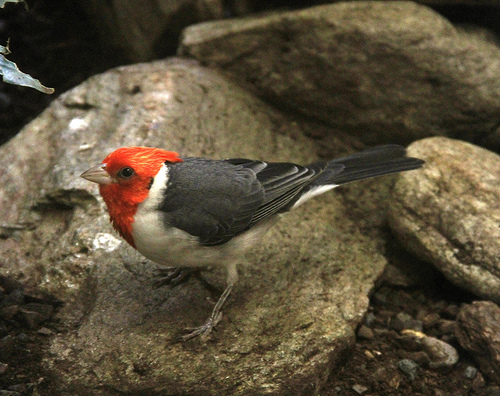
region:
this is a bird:
[55, 113, 431, 346]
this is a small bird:
[50, 113, 450, 365]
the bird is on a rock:
[60, 105, 467, 362]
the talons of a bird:
[155, 299, 266, 359]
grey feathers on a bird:
[172, 155, 368, 232]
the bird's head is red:
[67, 90, 463, 328]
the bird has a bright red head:
[51, 114, 204, 251]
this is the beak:
[81, 147, 113, 189]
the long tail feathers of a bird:
[300, 128, 435, 200]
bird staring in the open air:
[80, 152, 299, 303]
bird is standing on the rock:
[85, 116, 277, 329]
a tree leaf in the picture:
[2, 39, 48, 107]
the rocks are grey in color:
[48, 261, 178, 393]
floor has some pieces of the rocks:
[386, 292, 485, 393]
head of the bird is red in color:
[73, 143, 163, 205]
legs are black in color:
[161, 259, 237, 342]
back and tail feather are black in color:
[169, 161, 355, 210]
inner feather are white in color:
[118, 204, 265, 281]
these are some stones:
[148, 70, 355, 141]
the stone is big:
[161, 90, 237, 131]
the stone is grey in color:
[261, 272, 321, 337]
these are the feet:
[154, 262, 244, 348]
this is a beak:
[75, 157, 109, 188]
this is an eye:
[114, 164, 141, 181]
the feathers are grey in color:
[195, 165, 247, 218]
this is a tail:
[306, 137, 430, 206]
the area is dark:
[82, 38, 115, 53]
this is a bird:
[71, 130, 421, 307]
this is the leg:
[193, 277, 232, 329]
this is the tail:
[322, 133, 402, 191]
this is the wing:
[173, 175, 257, 226]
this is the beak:
[84, 167, 109, 181]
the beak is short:
[70, 159, 110, 195]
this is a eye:
[114, 165, 139, 179]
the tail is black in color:
[306, 150, 378, 185]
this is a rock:
[276, 16, 461, 64]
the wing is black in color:
[211, 166, 253, 201]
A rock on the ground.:
[364, 312, 379, 323]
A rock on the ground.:
[348, 319, 374, 340]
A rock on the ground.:
[397, 351, 414, 369]